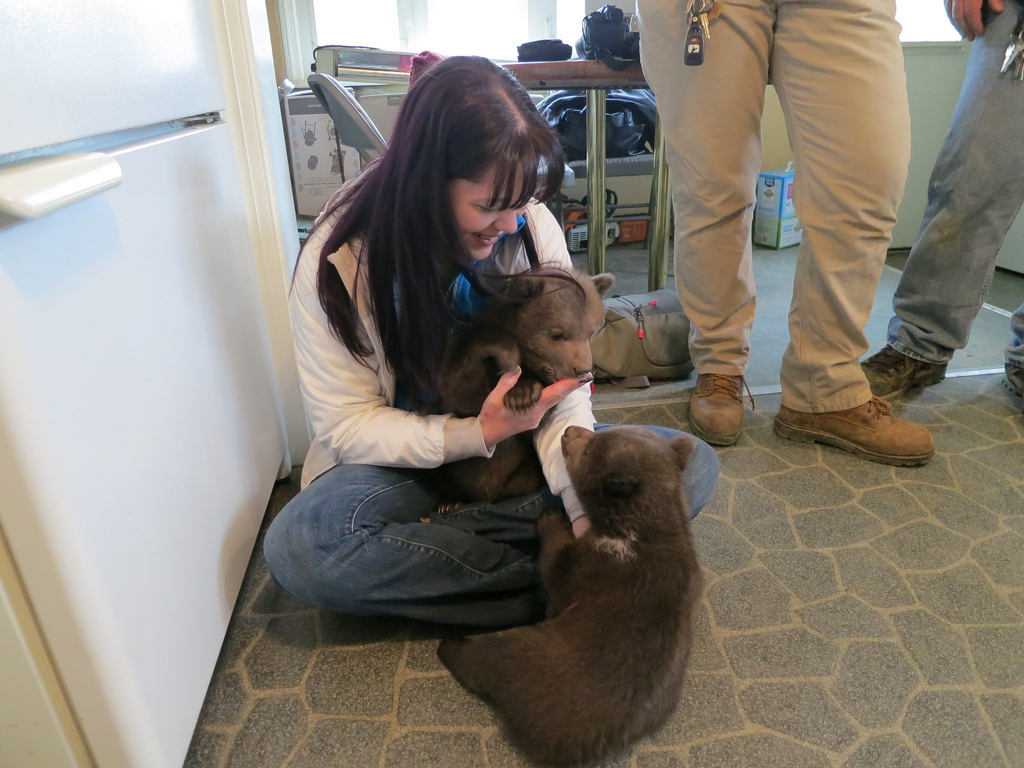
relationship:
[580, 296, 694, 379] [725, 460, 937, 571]
brown bag on ground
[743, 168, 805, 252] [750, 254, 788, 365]
box on ground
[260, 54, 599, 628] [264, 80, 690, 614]
lady in a sweater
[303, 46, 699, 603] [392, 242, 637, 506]
lady holding bear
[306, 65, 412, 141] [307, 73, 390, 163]
back of a back